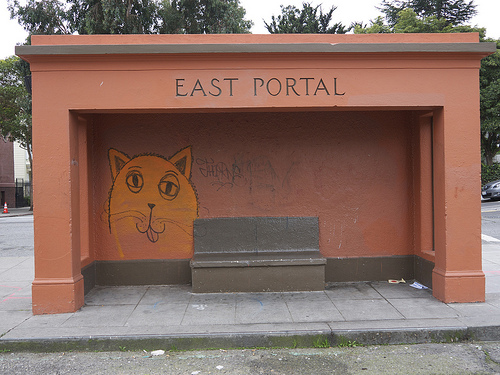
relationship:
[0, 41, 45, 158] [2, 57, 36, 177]
branch on tree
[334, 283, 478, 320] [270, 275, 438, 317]
litter on ground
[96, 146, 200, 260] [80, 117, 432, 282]
cat painted on wall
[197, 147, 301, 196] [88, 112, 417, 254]
graffiti on wall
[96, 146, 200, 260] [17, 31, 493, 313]
cat on building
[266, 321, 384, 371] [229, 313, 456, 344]
grass by curb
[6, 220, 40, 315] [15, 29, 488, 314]
sidewalk behind shelter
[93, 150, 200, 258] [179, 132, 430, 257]
graffitti on shelter wall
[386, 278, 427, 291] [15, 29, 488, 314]
litter in shelter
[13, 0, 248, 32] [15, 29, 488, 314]
tree behind shelter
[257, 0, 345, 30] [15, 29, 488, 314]
tree behind shelter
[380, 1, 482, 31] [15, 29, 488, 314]
tree behind shelter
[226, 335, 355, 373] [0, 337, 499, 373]
oil stain on concrete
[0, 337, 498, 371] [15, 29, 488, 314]
street in front of shelter